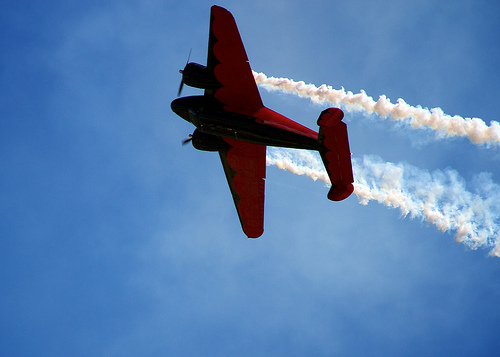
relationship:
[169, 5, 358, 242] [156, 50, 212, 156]
airplane has propellers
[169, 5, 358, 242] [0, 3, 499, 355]
airplane facing left in sky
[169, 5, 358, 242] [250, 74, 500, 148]
airplane leaving smoke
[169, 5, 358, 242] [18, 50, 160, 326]
airplane flying through sky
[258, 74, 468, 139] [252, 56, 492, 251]
smoke for skywriting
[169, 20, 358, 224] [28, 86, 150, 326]
airplane on sky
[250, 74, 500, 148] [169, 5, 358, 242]
smoke trailing behind airplane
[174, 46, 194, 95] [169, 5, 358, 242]
propeller on airplane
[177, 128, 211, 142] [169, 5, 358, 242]
propeller on airplane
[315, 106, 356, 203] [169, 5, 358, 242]
tail on airplane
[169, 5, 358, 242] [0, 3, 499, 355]
airplane in sky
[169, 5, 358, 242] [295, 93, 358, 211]
airplane has a tail